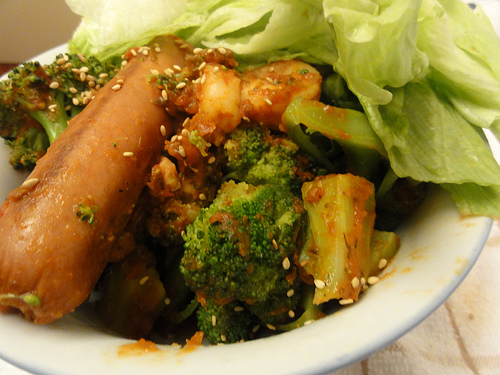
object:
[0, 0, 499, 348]
food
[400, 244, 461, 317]
plate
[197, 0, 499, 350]
vegetable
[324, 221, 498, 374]
table cloth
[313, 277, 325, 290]
seed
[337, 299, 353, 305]
seed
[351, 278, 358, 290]
seed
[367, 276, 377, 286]
seed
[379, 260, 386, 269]
seed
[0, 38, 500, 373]
white bowl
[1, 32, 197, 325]
carrot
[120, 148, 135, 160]
seed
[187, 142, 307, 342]
zebra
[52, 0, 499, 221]
lettuce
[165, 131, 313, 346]
broccoli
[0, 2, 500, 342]
food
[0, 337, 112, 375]
plate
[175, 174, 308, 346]
broccoli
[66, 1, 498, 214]
cabbage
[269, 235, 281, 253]
seeds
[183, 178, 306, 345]
broccoli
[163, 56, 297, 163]
sauce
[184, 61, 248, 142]
potatoes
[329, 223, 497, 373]
cloth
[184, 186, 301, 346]
broccoli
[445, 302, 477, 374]
line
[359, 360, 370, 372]
line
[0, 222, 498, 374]
table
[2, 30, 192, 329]
meat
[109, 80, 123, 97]
sesame seeds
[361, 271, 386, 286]
sesame seeds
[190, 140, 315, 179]
broccoi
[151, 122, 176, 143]
seeds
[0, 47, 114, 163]
broccoli